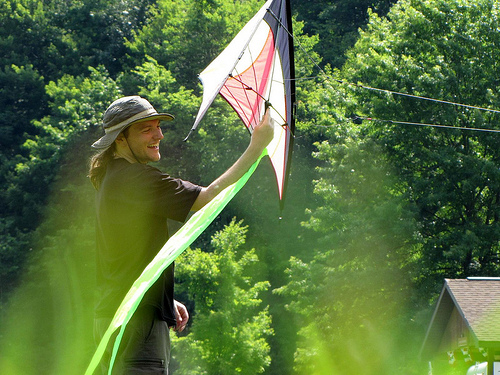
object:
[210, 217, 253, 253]
part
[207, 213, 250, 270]
branch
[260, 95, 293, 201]
part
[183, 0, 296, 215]
kite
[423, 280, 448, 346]
edge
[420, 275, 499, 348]
roof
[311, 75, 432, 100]
part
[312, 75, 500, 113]
zip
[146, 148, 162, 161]
chin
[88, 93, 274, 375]
man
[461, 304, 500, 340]
part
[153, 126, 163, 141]
nose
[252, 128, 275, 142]
part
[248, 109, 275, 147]
hand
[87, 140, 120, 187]
hair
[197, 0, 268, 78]
edge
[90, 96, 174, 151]
hat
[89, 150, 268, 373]
tail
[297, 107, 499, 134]
string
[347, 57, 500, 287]
trees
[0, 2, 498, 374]
background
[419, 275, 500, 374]
building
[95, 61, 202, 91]
top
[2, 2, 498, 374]
air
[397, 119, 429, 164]
leaves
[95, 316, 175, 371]
pants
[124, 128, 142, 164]
strap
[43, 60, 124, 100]
sunlight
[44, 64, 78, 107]
leaves